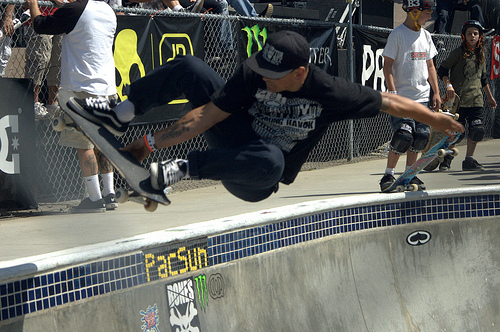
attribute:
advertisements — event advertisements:
[101, 1, 463, 132]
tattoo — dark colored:
[158, 122, 202, 142]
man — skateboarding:
[81, 19, 467, 224]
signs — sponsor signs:
[107, 12, 211, 124]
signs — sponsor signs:
[229, 17, 390, 99]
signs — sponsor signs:
[489, 32, 499, 78]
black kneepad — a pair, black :
[385, 122, 415, 155]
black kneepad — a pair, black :
[408, 121, 434, 153]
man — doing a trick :
[54, 36, 467, 232]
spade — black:
[401, 225, 453, 266]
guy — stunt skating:
[55, 23, 468, 226]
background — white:
[412, 232, 432, 235]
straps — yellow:
[399, 2, 435, 58]